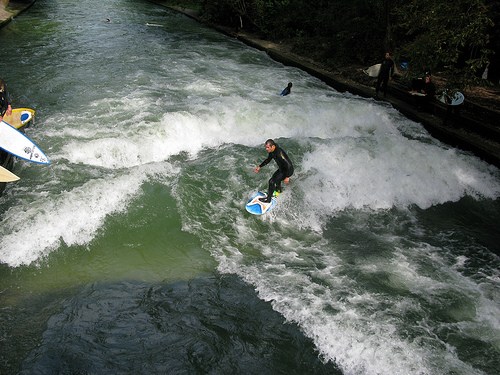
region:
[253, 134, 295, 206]
The man is wearing a wetsuit.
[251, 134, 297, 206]
The wetsuit is wet.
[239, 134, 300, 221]
The man is on a surfboard.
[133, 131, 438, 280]
The surfboard is in the water.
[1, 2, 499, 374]
The water is zealous.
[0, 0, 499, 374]
The water is wavy.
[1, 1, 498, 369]
The water is boisterous.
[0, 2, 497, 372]
The water tumultuous.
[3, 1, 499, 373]
The water is choppy.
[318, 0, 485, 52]
these are some trees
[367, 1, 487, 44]
the trees are tall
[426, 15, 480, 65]
the leaves are green in color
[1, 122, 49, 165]
this is a surfboard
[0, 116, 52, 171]
the surfboard is big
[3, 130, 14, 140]
the surfboard is white in color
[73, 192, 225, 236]
this is some water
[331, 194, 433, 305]
the water has some waves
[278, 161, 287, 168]
the swimsuit is black in color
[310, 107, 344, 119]
the water is white in color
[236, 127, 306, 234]
a man with surf board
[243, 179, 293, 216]
a blue colour surfboard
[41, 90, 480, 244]
a white colour big waves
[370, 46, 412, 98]
person standing near the water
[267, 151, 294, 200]
a man wearing black colour dress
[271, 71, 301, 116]
a person in the water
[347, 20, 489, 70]
trees near the water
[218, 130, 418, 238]
a person surfing near the waves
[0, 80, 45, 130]
a person standing in the yellow boat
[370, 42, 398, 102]
a black colour dressed man standing near the water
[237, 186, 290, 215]
The surfboard the man is standing on.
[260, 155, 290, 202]
The wet suit the man is wearing that is in the water.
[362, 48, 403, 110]
The man on the right holding a white surfboard.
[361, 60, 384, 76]
The white surfboard being held by the man on the right.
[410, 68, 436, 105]
The person sitting next to the guy on the right side of the stream.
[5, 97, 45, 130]
The yellow surfboard on the left.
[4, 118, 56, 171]
The white and blue surfboard on the left.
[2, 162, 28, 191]
The tip of the surfboard next to the white and blue one.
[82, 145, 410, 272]
The wave the surfer is riding.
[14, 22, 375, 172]
The water in the distance.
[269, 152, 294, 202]
black suit surfer is wearing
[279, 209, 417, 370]
wave caps are white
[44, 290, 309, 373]
water is dark blue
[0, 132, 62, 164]
boat is in water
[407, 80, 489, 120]
surfboard on the side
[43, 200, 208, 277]
water is green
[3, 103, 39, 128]
yellow boat in the water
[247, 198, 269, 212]
surfboard the man is on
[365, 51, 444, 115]
two people on the side